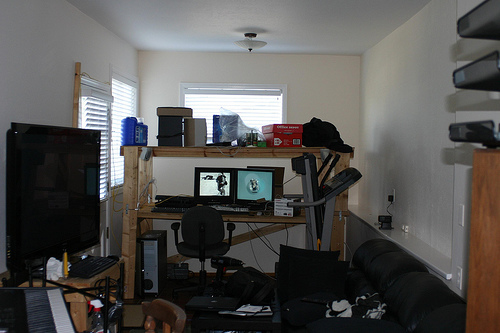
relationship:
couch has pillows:
[272, 232, 437, 331] [286, 254, 349, 301]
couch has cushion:
[272, 232, 437, 331] [360, 243, 406, 303]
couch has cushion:
[272, 232, 437, 331] [402, 280, 452, 330]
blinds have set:
[80, 78, 110, 199] [79, 75, 111, 197]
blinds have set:
[108, 71, 146, 190] [109, 79, 141, 189]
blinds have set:
[185, 92, 283, 143] [175, 82, 286, 146]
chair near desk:
[171, 202, 244, 300] [138, 186, 312, 305]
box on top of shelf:
[270, 120, 306, 149] [130, 141, 351, 161]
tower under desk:
[135, 224, 166, 299] [132, 199, 313, 299]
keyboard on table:
[69, 253, 120, 277] [8, 253, 126, 332]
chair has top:
[118, 292, 192, 331] [143, 300, 190, 331]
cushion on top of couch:
[353, 235, 422, 305] [276, 236, 463, 331]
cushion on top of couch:
[403, 270, 464, 330] [276, 236, 463, 331]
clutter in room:
[178, 116, 209, 147] [5, 2, 471, 319]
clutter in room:
[154, 105, 354, 154] [5, 2, 471, 319]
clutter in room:
[136, 218, 192, 298] [5, 2, 471, 319]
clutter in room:
[223, 253, 283, 320] [5, 2, 471, 319]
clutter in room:
[71, 275, 159, 331] [5, 2, 471, 319]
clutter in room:
[184, 265, 279, 322] [5, 2, 471, 319]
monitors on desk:
[190, 158, 280, 212] [129, 130, 338, 275]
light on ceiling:
[235, 21, 266, 56] [77, 0, 434, 89]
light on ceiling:
[235, 32, 268, 52] [69, 0, 429, 57]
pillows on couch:
[254, 231, 360, 323] [275, 229, 487, 329]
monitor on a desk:
[192, 164, 235, 202] [141, 193, 307, 239]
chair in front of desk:
[169, 206, 237, 299] [126, 193, 326, 279]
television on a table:
[2, 121, 104, 274] [8, 253, 122, 302]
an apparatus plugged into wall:
[375, 195, 396, 232] [366, 157, 418, 210]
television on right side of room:
[0, 118, 104, 270] [5, 2, 471, 319]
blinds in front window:
[182, 91, 277, 118] [177, 78, 285, 123]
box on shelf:
[261, 123, 304, 148] [135, 139, 345, 160]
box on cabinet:
[261, 123, 304, 148] [117, 140, 350, 293]